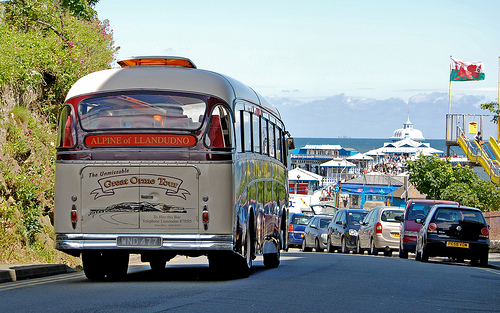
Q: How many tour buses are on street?
A: 1.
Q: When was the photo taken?
A: Daytime.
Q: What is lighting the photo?
A: Sun.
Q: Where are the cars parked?
A: On side of street.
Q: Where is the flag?
A: On flagpole.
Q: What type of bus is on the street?
A: Tour bus.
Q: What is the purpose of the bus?
A: To give tours.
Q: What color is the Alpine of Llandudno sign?
A: Red.